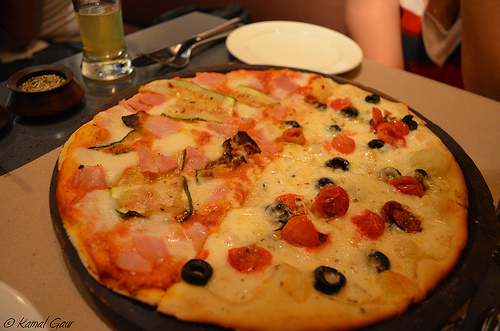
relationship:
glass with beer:
[75, 2, 139, 86] [77, 2, 125, 56]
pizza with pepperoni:
[57, 68, 471, 330] [283, 215, 329, 249]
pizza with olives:
[57, 68, 471, 330] [180, 257, 210, 284]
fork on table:
[137, 32, 230, 67] [1, 10, 498, 328]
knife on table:
[128, 18, 240, 68] [1, 10, 498, 328]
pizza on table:
[57, 68, 464, 330] [0, 49, 495, 323]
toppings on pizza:
[75, 70, 427, 296] [57, 68, 464, 330]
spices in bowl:
[14, 70, 63, 92] [5, 62, 77, 116]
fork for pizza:
[153, 53, 224, 77] [57, 85, 458, 320]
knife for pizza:
[128, 1, 240, 66] [57, 85, 458, 320]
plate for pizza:
[227, 5, 364, 78] [57, 85, 458, 320]